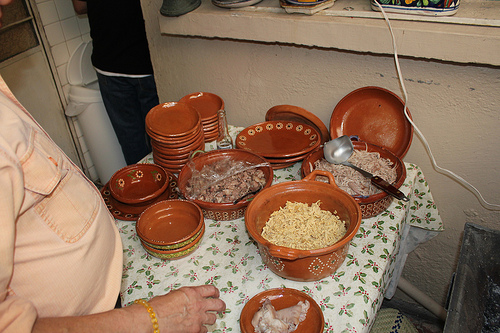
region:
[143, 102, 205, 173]
a stack of brown plates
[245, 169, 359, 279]
a large brown bowl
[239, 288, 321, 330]
a brown dinner plate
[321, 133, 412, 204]
a large serving spoon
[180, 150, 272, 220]
a large brown dish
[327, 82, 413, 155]
a large brown plate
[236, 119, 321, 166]
a stack of brown plates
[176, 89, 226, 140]
a stack of brown plates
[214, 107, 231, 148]
a clear glass bottle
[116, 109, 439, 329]
a Christmas themed tablecloth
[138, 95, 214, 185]
stack of small brown plates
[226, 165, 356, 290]
bowl of food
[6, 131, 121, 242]
light pink breast pocket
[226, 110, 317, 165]
stack of three big plates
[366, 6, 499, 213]
white cord running down the wall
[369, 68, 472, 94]
black marks on the wall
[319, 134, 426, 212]
ladle laying on the food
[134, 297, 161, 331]
yellow band around the wrist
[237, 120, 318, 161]
yellowish design around the edge of the plate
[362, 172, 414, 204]
handle of the ladle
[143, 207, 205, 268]
a small stack of bowls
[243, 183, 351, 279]
a bowl of rice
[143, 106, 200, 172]
a stack of suacers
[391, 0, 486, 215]
a white electrical cord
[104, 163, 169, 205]
a bowl with a floral print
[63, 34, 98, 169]
a white garbage can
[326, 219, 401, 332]
a table cloth with a floral print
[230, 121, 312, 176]
plates with a floral print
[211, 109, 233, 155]
a glass bottle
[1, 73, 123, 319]
a person wearing a peach colored shirt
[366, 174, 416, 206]
the handle is dark brown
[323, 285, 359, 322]
the tablecloth has missel toe on it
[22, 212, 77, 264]
the shirt is light orange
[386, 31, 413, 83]
the cord is white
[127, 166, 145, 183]
the bowl has sunflowers on it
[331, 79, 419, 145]
this bowl is plain brown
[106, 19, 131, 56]
the shirt is black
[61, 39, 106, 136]
the trash can is opened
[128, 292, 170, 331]
the braclet is yellow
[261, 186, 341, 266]
the noodles are in the pot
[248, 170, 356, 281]
rice in a brown pot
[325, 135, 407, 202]
a ladle on top of a bowl of food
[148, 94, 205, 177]
a stack of brown ceramic plates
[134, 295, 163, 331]
an orange bracelet on a person's wrist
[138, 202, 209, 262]
a stack of brown and green bowls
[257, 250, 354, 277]
a diamond design on a brown pot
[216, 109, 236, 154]
an empty beer bottle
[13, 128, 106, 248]
a pocket on a mans shirt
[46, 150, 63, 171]
a button hole on a pocket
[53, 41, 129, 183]
a white trash can